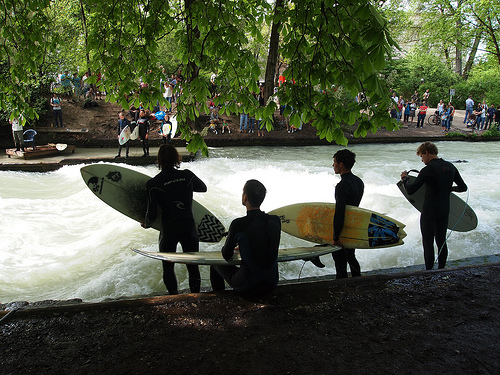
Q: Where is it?
A: This is at the river.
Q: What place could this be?
A: It is a river.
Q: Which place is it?
A: It is a river.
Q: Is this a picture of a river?
A: Yes, it is showing a river.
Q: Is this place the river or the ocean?
A: It is the river.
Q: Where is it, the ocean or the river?
A: It is the river.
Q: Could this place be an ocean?
A: No, it is a river.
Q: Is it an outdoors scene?
A: Yes, it is outdoors.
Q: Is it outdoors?
A: Yes, it is outdoors.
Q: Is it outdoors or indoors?
A: It is outdoors.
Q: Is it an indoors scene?
A: No, it is outdoors.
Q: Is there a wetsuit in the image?
A: Yes, there is a wetsuit.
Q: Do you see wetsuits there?
A: Yes, there is a wetsuit.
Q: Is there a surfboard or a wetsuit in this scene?
A: Yes, there is a wetsuit.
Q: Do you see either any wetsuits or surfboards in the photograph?
A: Yes, there is a wetsuit.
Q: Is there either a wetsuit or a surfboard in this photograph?
A: Yes, there is a wetsuit.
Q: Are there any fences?
A: No, there are no fences.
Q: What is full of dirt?
A: The ground is full of dirt.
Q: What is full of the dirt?
A: The ground is full of dirt.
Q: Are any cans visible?
A: No, there are no cans.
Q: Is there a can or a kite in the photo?
A: No, there are no cans or kites.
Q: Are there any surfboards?
A: Yes, there is a surfboard.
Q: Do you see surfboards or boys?
A: Yes, there is a surfboard.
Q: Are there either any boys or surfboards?
A: Yes, there is a surfboard.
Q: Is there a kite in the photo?
A: No, there are no kites.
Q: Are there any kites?
A: No, there are no kites.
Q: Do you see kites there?
A: No, there are no kites.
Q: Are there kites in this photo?
A: No, there are no kites.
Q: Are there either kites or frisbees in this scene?
A: No, there are no kites or frisbees.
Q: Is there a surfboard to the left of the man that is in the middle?
A: Yes, there is a surfboard to the left of the man.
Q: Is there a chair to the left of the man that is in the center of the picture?
A: No, there is a surfboard to the left of the man.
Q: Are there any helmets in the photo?
A: No, there are no helmets.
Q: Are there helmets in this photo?
A: No, there are no helmets.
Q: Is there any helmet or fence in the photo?
A: No, there are no helmets or fences.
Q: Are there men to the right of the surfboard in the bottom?
A: Yes, there is a man to the right of the surfboard.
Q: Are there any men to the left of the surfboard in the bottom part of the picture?
A: No, the man is to the right of the surfboard.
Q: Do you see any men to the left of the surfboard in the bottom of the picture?
A: No, the man is to the right of the surfboard.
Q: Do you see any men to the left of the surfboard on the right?
A: Yes, there is a man to the left of the surfboard.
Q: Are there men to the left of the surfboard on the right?
A: Yes, there is a man to the left of the surfboard.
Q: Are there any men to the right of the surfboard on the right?
A: No, the man is to the left of the surf board.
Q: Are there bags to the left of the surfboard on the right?
A: No, there is a man to the left of the surfboard.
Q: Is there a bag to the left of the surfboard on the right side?
A: No, there is a man to the left of the surfboard.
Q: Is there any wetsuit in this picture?
A: Yes, there is a wetsuit.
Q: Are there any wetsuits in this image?
A: Yes, there is a wetsuit.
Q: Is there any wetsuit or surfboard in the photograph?
A: Yes, there is a wetsuit.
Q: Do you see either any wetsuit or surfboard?
A: Yes, there is a wetsuit.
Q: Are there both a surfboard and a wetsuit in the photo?
A: Yes, there are both a wetsuit and a surfboard.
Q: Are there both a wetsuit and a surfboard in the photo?
A: Yes, there are both a wetsuit and a surfboard.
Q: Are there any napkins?
A: No, there are no napkins.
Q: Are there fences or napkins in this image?
A: No, there are no napkins or fences.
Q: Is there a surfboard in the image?
A: Yes, there is a surfboard.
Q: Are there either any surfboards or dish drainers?
A: Yes, there is a surfboard.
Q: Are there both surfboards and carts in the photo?
A: No, there is a surfboard but no carts.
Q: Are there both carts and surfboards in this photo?
A: No, there is a surfboard but no carts.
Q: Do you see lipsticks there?
A: No, there are no lipsticks.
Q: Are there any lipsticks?
A: No, there are no lipsticks.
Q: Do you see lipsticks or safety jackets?
A: No, there are no lipsticks or safety jackets.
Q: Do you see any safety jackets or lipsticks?
A: No, there are no lipsticks or safety jackets.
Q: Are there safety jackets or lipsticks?
A: No, there are no lipsticks or safety jackets.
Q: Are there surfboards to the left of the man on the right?
A: Yes, there is a surfboard to the left of the man.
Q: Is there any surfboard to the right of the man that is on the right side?
A: No, the surfboard is to the left of the man.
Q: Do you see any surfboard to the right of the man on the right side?
A: No, the surfboard is to the left of the man.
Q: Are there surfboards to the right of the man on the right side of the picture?
A: No, the surfboard is to the left of the man.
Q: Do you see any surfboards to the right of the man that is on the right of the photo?
A: No, the surfboard is to the left of the man.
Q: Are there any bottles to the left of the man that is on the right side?
A: No, there is a surfboard to the left of the man.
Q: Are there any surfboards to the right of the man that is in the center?
A: Yes, there is a surfboard to the right of the man.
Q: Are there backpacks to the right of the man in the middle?
A: No, there is a surfboard to the right of the man.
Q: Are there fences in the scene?
A: No, there are no fences.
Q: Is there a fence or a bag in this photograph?
A: No, there are no fences or bags.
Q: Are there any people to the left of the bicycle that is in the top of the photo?
A: Yes, there is a person to the left of the bicycle.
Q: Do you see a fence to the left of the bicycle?
A: No, there is a person to the left of the bicycle.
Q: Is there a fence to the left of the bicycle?
A: No, there is a person to the left of the bicycle.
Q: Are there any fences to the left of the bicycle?
A: No, there is a person to the left of the bicycle.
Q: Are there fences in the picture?
A: No, there are no fences.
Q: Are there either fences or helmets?
A: No, there are no fences or helmets.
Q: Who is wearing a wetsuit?
A: The man is wearing a wetsuit.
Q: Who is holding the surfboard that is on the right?
A: The man is holding the surfboard.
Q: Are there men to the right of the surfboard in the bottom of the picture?
A: Yes, there is a man to the right of the surfboard.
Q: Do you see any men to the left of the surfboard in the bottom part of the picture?
A: No, the man is to the right of the surfboard.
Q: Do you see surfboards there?
A: Yes, there is a surfboard.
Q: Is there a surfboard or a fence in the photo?
A: Yes, there is a surfboard.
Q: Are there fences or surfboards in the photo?
A: Yes, there is a surfboard.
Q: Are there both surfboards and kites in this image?
A: No, there is a surfboard but no kites.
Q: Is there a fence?
A: No, there are no fences.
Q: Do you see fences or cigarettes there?
A: No, there are no fences or cigarettes.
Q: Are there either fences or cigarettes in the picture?
A: No, there are no fences or cigarettes.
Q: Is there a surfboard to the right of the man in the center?
A: Yes, there is a surfboard to the right of the man.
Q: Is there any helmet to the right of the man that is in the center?
A: No, there is a surfboard to the right of the man.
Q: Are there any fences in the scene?
A: No, there are no fences.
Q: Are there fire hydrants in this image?
A: No, there are no fire hydrants.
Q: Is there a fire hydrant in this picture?
A: No, there are no fire hydrants.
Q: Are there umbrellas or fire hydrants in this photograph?
A: No, there are no fire hydrants or umbrellas.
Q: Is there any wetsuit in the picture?
A: Yes, there is a wetsuit.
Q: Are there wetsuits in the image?
A: Yes, there is a wetsuit.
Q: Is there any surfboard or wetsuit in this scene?
A: Yes, there is a wetsuit.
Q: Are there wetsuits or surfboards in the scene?
A: Yes, there is a wetsuit.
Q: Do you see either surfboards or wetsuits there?
A: Yes, there is a wetsuit.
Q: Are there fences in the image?
A: No, there are no fences.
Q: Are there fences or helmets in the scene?
A: No, there are no fences or helmets.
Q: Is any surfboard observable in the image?
A: Yes, there is a surfboard.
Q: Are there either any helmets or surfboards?
A: Yes, there is a surfboard.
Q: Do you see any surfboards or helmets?
A: Yes, there is a surfboard.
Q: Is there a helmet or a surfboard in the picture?
A: Yes, there is a surfboard.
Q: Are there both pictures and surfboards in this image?
A: No, there is a surfboard but no pictures.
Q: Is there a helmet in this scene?
A: No, there are no helmets.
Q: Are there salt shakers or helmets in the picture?
A: No, there are no helmets or salt shakers.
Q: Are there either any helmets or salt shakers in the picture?
A: No, there are no helmets or salt shakers.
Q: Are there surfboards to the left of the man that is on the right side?
A: Yes, there is a surfboard to the left of the man.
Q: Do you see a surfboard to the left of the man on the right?
A: Yes, there is a surfboard to the left of the man.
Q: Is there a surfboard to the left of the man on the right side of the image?
A: Yes, there is a surfboard to the left of the man.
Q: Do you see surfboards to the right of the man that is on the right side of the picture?
A: No, the surfboard is to the left of the man.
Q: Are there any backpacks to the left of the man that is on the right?
A: No, there is a surfboard to the left of the man.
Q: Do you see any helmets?
A: No, there are no helmets.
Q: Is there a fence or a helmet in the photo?
A: No, there are no helmets or fences.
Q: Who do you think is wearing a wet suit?
A: The man is wearing a wet suit.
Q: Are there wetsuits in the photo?
A: Yes, there is a wetsuit.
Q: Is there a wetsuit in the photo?
A: Yes, there is a wetsuit.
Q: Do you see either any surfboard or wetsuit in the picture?
A: Yes, there is a wetsuit.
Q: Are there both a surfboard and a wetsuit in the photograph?
A: Yes, there are both a wetsuit and a surfboard.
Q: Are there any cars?
A: No, there are no cars.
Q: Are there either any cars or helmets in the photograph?
A: No, there are no cars or helmets.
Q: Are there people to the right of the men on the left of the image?
A: Yes, there is a person to the right of the men.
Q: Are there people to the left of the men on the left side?
A: No, the person is to the right of the men.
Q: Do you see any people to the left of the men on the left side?
A: No, the person is to the right of the men.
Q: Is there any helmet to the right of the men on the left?
A: No, there is a person to the right of the men.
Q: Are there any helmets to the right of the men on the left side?
A: No, there is a person to the right of the men.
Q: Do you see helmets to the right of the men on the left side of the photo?
A: No, there is a person to the right of the men.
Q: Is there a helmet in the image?
A: No, there are no helmets.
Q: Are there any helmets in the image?
A: No, there are no helmets.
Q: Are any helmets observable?
A: No, there are no helmets.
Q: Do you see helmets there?
A: No, there are no helmets.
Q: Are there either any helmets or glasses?
A: No, there are no helmets or glasses.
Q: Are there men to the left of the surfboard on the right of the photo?
A: Yes, there is a man to the left of the surfboard.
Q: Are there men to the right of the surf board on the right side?
A: No, the man is to the left of the surfboard.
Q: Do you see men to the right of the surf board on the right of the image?
A: No, the man is to the left of the surfboard.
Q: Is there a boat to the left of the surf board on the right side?
A: No, there is a man to the left of the surfboard.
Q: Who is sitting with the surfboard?
A: The man is sitting with the surfboard.